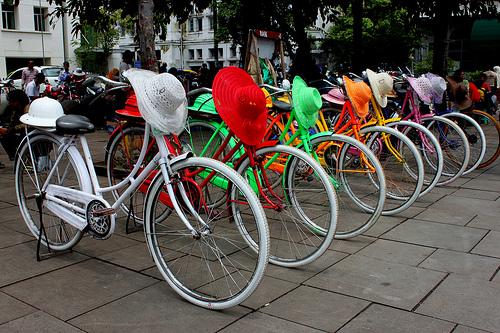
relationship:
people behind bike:
[17, 65, 100, 95] [27, 100, 252, 304]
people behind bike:
[17, 65, 100, 95] [212, 88, 322, 245]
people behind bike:
[17, 65, 100, 95] [290, 94, 385, 218]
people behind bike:
[17, 65, 100, 95] [332, 90, 422, 190]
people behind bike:
[17, 65, 100, 95] [400, 71, 467, 163]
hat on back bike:
[12, 87, 77, 128] [11, 86, 274, 313]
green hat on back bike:
[292, 75, 323, 129] [161, 81, 390, 243]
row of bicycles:
[12, 60, 495, 312] [51, 69, 468, 288]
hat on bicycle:
[12, 65, 448, 145] [6, 78, 274, 312]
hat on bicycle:
[12, 65, 448, 145] [92, 80, 342, 278]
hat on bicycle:
[12, 65, 448, 145] [245, 84, 435, 216]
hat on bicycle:
[12, 65, 448, 145] [385, 75, 475, 189]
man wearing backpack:
[438, 69, 487, 150] [484, 87, 494, 113]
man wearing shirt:
[453, 69, 478, 117] [448, 83, 475, 106]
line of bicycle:
[6, 71, 496, 312] [15, 66, 500, 311]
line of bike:
[6, 71, 496, 312] [11, 86, 274, 313]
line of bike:
[6, 71, 496, 312] [100, 90, 340, 270]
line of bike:
[6, 71, 496, 312] [161, 81, 390, 243]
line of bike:
[6, 71, 496, 312] [226, 74, 423, 219]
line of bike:
[6, 71, 496, 312] [281, 67, 440, 200]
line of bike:
[6, 71, 496, 312] [356, 71, 464, 187]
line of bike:
[6, 71, 496, 312] [411, 74, 489, 179]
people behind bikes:
[21, 59, 119, 99] [94, 57, 464, 278]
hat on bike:
[12, 65, 448, 145] [11, 86, 274, 313]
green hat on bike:
[292, 75, 323, 129] [161, 81, 390, 243]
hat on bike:
[12, 65, 448, 145] [161, 81, 390, 243]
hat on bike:
[12, 65, 448, 145] [269, 82, 426, 218]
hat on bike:
[12, 65, 448, 145] [351, 67, 480, 193]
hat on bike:
[12, 65, 448, 145] [388, 85, 481, 176]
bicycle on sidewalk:
[104, 101, 342, 269] [6, 125, 498, 331]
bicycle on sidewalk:
[192, 88, 387, 234] [6, 125, 498, 331]